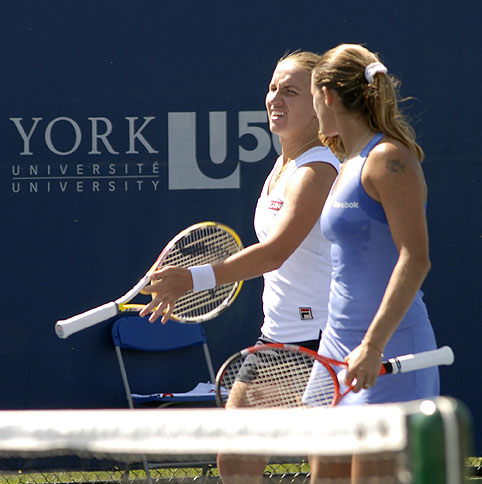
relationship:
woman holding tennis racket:
[310, 44, 423, 402] [221, 343, 365, 405]